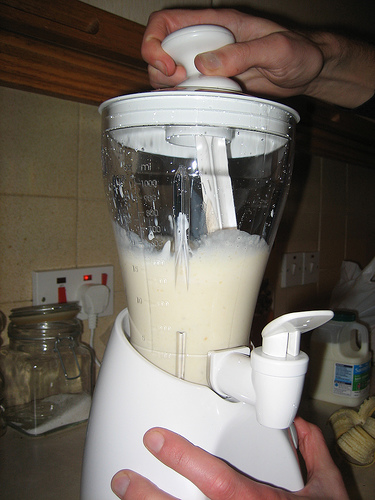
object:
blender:
[79, 23, 306, 498]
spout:
[245, 306, 329, 424]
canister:
[0, 300, 96, 440]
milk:
[316, 340, 368, 408]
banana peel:
[329, 408, 375, 464]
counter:
[0, 394, 375, 500]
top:
[95, 25, 302, 131]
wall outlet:
[30, 264, 113, 323]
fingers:
[192, 31, 284, 77]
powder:
[31, 402, 94, 435]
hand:
[140, 8, 324, 102]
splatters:
[104, 136, 189, 206]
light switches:
[282, 250, 302, 289]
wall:
[0, 83, 375, 411]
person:
[111, 5, 375, 500]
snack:
[151, 262, 242, 334]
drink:
[115, 225, 271, 394]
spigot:
[204, 340, 250, 402]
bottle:
[304, 305, 370, 408]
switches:
[304, 253, 325, 287]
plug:
[81, 284, 111, 315]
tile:
[0, 197, 76, 300]